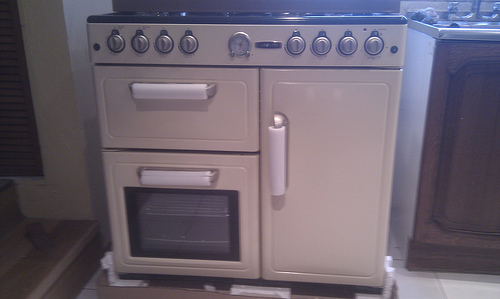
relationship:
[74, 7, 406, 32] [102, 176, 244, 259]
stove and oven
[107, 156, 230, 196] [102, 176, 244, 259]
door of oven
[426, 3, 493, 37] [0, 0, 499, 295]
sink in room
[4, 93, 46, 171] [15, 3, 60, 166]
shutters attached to window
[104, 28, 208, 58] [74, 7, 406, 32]
knobs attached to stove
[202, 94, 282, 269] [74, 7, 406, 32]
doors attached to stove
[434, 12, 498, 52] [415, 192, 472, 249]
board for cups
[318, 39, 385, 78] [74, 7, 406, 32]
dials attached to stove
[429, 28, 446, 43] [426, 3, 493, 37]
part of sink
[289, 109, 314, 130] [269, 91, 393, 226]
part of cabinet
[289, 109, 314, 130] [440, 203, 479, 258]
part of open door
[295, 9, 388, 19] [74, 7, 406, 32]
burners on top of stove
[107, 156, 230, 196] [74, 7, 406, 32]
door on stove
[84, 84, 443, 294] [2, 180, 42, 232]
room next to another room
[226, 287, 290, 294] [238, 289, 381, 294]
foam inside of box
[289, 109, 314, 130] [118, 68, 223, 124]
part of handle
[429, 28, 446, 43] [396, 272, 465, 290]
part of floor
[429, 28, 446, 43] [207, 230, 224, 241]
part of glass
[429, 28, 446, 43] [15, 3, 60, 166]
part of window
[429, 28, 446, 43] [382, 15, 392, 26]
part of edge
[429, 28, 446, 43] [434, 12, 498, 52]
part of board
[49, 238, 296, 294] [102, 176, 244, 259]
styrofoam at bottom of oven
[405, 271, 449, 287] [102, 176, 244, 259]
tile on right of oven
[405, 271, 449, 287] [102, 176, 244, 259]
tile on left of oven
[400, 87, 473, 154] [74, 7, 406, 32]
wood stains next to stove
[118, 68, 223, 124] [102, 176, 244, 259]
handle on oven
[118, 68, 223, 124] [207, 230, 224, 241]
handle on glass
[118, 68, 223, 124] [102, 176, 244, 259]
handle near top of oven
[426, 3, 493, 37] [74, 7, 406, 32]
sink next to stove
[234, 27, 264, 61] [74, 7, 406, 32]
temp gauge attached to stove